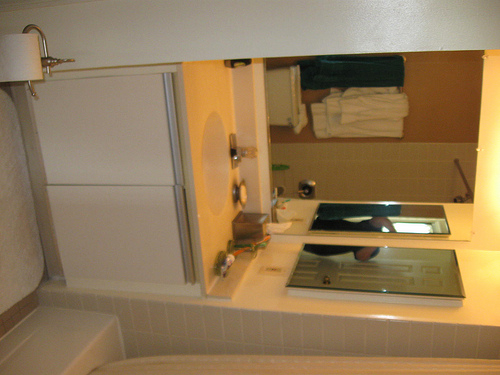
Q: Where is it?
A: This is at the bathroom.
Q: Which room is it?
A: It is a bathroom.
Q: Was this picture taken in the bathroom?
A: Yes, it was taken in the bathroom.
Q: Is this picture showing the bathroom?
A: Yes, it is showing the bathroom.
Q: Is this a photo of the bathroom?
A: Yes, it is showing the bathroom.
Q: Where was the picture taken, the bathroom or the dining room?
A: It was taken at the bathroom.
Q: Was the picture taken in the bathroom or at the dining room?
A: It was taken at the bathroom.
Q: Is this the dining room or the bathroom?
A: It is the bathroom.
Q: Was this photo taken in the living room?
A: No, the picture was taken in the bathroom.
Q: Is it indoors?
A: Yes, it is indoors.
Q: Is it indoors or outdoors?
A: It is indoors.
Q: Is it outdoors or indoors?
A: It is indoors.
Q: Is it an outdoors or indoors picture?
A: It is indoors.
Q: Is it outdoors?
A: No, it is indoors.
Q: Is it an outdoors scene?
A: No, it is indoors.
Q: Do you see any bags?
A: No, there are no bags.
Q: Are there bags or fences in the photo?
A: No, there are no bags or fences.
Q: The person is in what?
A: The person is in the cabinet.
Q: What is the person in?
A: The person is in the cabinet.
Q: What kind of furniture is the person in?
A: The person is in the cabinet.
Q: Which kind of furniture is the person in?
A: The person is in the cabinet.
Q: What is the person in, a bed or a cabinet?
A: The person is in a cabinet.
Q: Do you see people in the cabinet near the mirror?
A: Yes, there is a person in the cabinet.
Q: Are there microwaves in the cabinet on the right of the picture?
A: No, there is a person in the cabinet.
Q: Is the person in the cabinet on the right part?
A: Yes, the person is in the cabinet.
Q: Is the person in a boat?
A: No, the person is in the cabinet.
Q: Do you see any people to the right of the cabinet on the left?
A: Yes, there is a person to the right of the cabinet.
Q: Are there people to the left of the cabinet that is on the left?
A: No, the person is to the right of the cabinet.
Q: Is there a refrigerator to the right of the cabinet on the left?
A: No, there is a person to the right of the cabinet.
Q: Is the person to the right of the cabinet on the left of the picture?
A: Yes, the person is to the right of the cabinet.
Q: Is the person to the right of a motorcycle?
A: No, the person is to the right of the cabinet.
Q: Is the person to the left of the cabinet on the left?
A: No, the person is to the right of the cabinet.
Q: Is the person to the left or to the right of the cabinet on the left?
A: The person is to the right of the cabinet.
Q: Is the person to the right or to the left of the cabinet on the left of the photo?
A: The person is to the right of the cabinet.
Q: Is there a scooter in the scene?
A: No, there are no scooters.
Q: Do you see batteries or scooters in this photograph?
A: No, there are no scooters or batteries.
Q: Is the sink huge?
A: Yes, the sink is huge.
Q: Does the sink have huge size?
A: Yes, the sink is huge.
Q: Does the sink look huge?
A: Yes, the sink is huge.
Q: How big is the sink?
A: The sink is huge.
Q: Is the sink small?
A: No, the sink is huge.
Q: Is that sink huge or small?
A: The sink is huge.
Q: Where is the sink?
A: The sink is in the bathroom.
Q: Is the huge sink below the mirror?
A: Yes, the sink is below the mirror.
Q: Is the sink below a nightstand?
A: No, the sink is below the mirror.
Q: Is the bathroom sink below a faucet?
A: Yes, the sink is below a faucet.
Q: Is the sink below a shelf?
A: No, the sink is below a faucet.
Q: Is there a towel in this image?
A: Yes, there is a towel.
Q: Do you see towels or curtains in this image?
A: Yes, there is a towel.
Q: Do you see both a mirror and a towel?
A: Yes, there are both a towel and a mirror.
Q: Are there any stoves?
A: No, there are no stoves.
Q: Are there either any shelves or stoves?
A: No, there are no stoves or shelves.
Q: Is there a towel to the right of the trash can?
A: Yes, there is a towel to the right of the trash can.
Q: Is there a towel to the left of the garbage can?
A: No, the towel is to the right of the garbage can.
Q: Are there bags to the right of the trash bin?
A: No, there is a towel to the right of the trash bin.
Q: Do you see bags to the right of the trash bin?
A: No, there is a towel to the right of the trash bin.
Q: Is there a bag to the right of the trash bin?
A: No, there is a towel to the right of the trash bin.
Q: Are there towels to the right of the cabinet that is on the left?
A: Yes, there is a towel to the right of the cabinet.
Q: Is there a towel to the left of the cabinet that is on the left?
A: No, the towel is to the right of the cabinet.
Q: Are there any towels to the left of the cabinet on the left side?
A: No, the towel is to the right of the cabinet.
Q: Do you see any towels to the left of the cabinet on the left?
A: No, the towel is to the right of the cabinet.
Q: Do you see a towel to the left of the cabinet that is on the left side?
A: No, the towel is to the right of the cabinet.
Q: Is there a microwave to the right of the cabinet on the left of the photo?
A: No, there is a towel to the right of the cabinet.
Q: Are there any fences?
A: No, there are no fences.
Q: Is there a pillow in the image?
A: No, there are no pillows.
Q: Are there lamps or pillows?
A: No, there are no pillows or lamps.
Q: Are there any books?
A: No, there are no books.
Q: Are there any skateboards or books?
A: No, there are no books or skateboards.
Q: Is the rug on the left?
A: Yes, the rug is on the left of the image.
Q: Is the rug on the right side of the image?
A: No, the rug is on the left of the image.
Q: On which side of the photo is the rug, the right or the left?
A: The rug is on the left of the image.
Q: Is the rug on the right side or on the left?
A: The rug is on the left of the image.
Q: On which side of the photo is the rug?
A: The rug is on the left of the image.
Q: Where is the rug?
A: The rug is on the floor.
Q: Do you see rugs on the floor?
A: Yes, there is a rug on the floor.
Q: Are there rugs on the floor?
A: Yes, there is a rug on the floor.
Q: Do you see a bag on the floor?
A: No, there is a rug on the floor.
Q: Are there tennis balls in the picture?
A: No, there are no tennis balls.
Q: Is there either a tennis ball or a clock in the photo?
A: No, there are no tennis balls or clocks.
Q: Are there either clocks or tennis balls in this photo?
A: No, there are no tennis balls or clocks.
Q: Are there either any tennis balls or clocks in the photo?
A: No, there are no tennis balls or clocks.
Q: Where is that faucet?
A: The faucet is in the bathroom.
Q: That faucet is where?
A: The faucet is in the bathroom.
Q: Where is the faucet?
A: The faucet is in the bathroom.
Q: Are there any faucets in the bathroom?
A: Yes, there is a faucet in the bathroom.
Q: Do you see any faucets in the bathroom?
A: Yes, there is a faucet in the bathroom.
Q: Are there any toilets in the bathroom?
A: No, there is a faucet in the bathroom.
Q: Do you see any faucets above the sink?
A: Yes, there is a faucet above the sink.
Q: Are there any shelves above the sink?
A: No, there is a faucet above the sink.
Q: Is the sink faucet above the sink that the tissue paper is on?
A: Yes, the tap is above the sink.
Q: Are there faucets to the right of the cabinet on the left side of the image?
A: Yes, there is a faucet to the right of the cabinet.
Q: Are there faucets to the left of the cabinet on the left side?
A: No, the faucet is to the right of the cabinet.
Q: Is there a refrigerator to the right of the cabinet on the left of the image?
A: No, there is a faucet to the right of the cabinet.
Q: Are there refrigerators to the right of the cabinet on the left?
A: No, there is a faucet to the right of the cabinet.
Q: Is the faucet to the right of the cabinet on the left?
A: Yes, the faucet is to the right of the cabinet.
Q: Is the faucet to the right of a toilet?
A: No, the faucet is to the right of the cabinet.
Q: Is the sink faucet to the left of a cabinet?
A: No, the tap is to the right of a cabinet.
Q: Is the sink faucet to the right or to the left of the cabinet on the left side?
A: The tap is to the right of the cabinet.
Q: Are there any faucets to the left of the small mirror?
A: Yes, there is a faucet to the left of the mirror.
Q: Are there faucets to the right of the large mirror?
A: No, the faucet is to the left of the mirror.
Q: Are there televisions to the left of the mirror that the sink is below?
A: No, there is a faucet to the left of the mirror.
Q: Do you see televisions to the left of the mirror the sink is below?
A: No, there is a faucet to the left of the mirror.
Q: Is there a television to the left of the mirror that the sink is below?
A: No, there is a faucet to the left of the mirror.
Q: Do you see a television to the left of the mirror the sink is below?
A: No, there is a faucet to the left of the mirror.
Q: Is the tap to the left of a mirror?
A: Yes, the tap is to the left of a mirror.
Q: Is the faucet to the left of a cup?
A: No, the faucet is to the left of a mirror.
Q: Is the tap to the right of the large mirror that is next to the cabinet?
A: No, the tap is to the left of the mirror.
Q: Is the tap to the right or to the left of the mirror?
A: The tap is to the left of the mirror.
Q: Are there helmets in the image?
A: No, there are no helmets.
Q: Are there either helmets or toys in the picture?
A: No, there are no helmets or toys.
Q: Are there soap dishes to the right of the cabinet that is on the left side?
A: Yes, there is a soap dish to the right of the cabinet.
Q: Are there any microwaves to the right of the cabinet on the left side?
A: No, there is a soap dish to the right of the cabinet.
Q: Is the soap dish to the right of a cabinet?
A: Yes, the soap dish is to the right of a cabinet.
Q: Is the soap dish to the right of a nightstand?
A: No, the soap dish is to the right of a cabinet.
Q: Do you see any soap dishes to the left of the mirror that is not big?
A: Yes, there is a soap dish to the left of the mirror.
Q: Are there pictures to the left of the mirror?
A: No, there is a soap dish to the left of the mirror.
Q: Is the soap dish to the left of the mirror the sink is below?
A: Yes, the soap dish is to the left of the mirror.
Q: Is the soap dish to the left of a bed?
A: No, the soap dish is to the left of the mirror.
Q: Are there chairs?
A: No, there are no chairs.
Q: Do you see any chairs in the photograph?
A: No, there are no chairs.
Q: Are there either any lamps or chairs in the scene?
A: No, there are no chairs or lamps.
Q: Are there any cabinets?
A: Yes, there is a cabinet.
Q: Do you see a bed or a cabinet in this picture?
A: Yes, there is a cabinet.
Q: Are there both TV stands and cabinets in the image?
A: No, there is a cabinet but no TV stands.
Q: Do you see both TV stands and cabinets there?
A: No, there is a cabinet but no TV stands.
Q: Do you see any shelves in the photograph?
A: No, there are no shelves.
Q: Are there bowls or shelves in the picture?
A: No, there are no shelves or bowls.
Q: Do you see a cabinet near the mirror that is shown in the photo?
A: Yes, there is a cabinet near the mirror.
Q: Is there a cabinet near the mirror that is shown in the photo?
A: Yes, there is a cabinet near the mirror.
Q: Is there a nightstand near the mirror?
A: No, there is a cabinet near the mirror.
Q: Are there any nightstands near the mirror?
A: No, there is a cabinet near the mirror.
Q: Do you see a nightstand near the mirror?
A: No, there is a cabinet near the mirror.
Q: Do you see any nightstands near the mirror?
A: No, there is a cabinet near the mirror.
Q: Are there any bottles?
A: No, there are no bottles.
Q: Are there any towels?
A: Yes, there is a towel.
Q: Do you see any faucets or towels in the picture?
A: Yes, there is a towel.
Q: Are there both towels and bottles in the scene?
A: No, there is a towel but no bottles.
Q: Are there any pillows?
A: No, there are no pillows.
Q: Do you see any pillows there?
A: No, there are no pillows.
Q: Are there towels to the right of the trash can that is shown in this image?
A: Yes, there is a towel to the right of the trash can.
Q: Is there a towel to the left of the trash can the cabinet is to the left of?
A: No, the towel is to the right of the garbage bin.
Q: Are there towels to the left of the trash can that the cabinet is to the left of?
A: No, the towel is to the right of the garbage bin.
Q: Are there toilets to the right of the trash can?
A: No, there is a towel to the right of the trash can.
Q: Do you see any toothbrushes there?
A: No, there are no toothbrushes.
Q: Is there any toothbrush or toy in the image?
A: No, there are no toothbrushes or toys.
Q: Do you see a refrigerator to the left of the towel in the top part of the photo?
A: No, there is a trash can to the left of the towel.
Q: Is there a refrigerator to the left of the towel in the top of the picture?
A: No, there is a trash can to the left of the towel.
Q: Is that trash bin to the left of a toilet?
A: No, the trash bin is to the left of the towel.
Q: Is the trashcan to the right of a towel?
A: No, the trashcan is to the left of a towel.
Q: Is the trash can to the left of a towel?
A: Yes, the trash can is to the left of a towel.